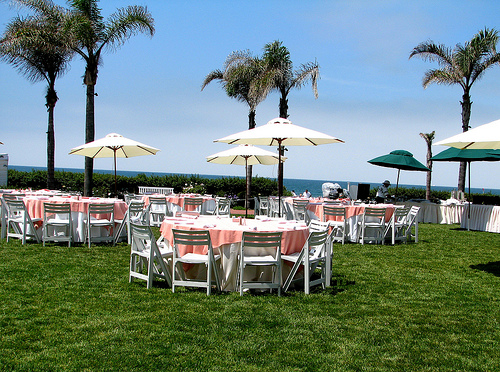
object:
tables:
[23, 196, 128, 243]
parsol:
[213, 117, 344, 218]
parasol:
[367, 150, 432, 205]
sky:
[0, 0, 494, 181]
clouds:
[86, 77, 399, 162]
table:
[158, 217, 309, 294]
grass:
[0, 246, 485, 372]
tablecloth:
[396, 202, 465, 226]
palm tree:
[200, 50, 294, 209]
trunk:
[44, 85, 59, 191]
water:
[8, 151, 499, 198]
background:
[0, 98, 499, 213]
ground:
[0, 186, 500, 372]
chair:
[172, 229, 221, 297]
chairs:
[129, 221, 181, 289]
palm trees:
[0, 0, 155, 196]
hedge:
[8, 168, 294, 209]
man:
[374, 180, 395, 204]